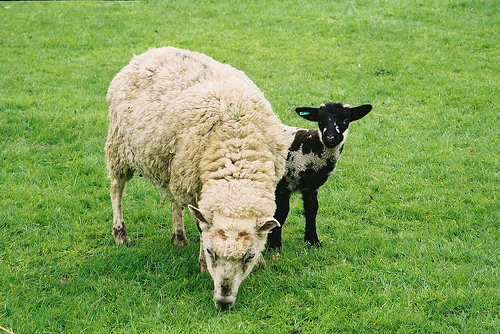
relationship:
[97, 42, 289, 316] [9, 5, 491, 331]
sheep in field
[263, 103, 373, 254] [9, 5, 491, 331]
sheep in field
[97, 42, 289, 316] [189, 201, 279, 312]
sheep has head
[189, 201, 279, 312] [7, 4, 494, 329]
head in grass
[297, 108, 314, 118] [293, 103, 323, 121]
tag on ear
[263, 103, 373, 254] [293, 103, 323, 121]
sheep has ear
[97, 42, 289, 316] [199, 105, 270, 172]
sheep has fur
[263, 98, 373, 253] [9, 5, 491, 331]
sheep in field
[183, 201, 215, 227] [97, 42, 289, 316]
ear on sheep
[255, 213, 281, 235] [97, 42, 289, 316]
ear on sheep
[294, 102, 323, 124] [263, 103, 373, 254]
ear on sheep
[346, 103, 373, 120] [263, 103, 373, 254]
ear on sheep